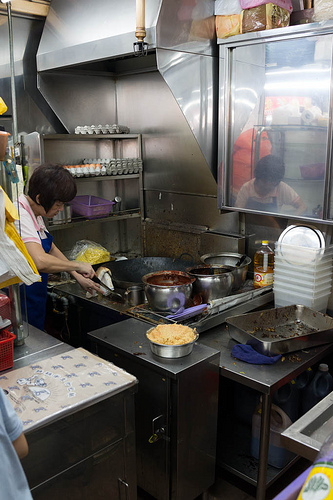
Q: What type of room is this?
A: Kitchen.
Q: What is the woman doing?
A: Cutting food.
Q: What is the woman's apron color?
A: Blue.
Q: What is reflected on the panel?
A: Cook.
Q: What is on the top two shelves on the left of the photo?
A: Eggs.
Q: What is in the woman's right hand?
A: Knife.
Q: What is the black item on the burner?
A: Wok.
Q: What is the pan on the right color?
A: Silver.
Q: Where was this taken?
A: A restaurant kitchen.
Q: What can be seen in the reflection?
A: A woman cooking.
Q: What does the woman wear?
A: A blue apron.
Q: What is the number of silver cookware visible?
A: Five.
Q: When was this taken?
A: Daytime.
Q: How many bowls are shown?
A: 4.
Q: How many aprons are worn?
A: 1.